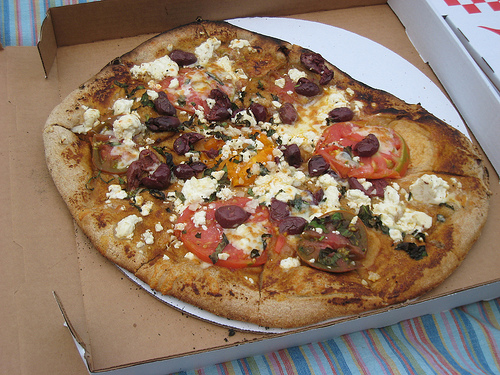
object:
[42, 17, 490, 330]
pizza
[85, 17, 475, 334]
plate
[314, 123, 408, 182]
tomato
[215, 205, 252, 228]
olives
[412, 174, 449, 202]
cheese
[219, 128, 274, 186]
pepper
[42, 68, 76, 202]
crust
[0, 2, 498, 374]
box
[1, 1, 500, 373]
cloth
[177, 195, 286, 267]
toppings